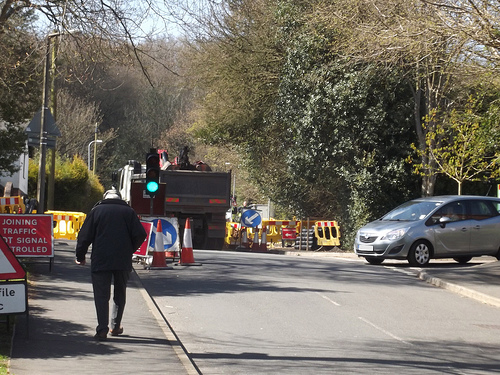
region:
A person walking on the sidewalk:
[74, 181, 149, 339]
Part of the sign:
[248, 211, 257, 221]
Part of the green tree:
[306, 165, 358, 198]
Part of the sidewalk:
[63, 350, 99, 364]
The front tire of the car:
[408, 238, 433, 267]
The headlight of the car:
[378, 227, 408, 242]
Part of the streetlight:
[93, 136, 104, 145]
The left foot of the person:
[93, 323, 110, 340]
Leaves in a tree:
[362, 50, 407, 78]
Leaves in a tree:
[333, 173, 405, 209]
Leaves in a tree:
[356, 144, 418, 183]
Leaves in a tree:
[282, 137, 347, 172]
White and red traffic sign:
[6, 211, 64, 272]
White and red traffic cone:
[178, 216, 192, 265]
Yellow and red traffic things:
[225, 211, 335, 253]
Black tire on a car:
[408, 243, 428, 262]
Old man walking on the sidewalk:
[74, 186, 143, 338]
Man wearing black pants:
[87, 263, 137, 338]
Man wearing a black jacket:
[75, 193, 150, 269]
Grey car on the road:
[350, 183, 498, 280]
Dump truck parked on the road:
[112, 148, 239, 250]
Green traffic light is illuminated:
[140, 150, 167, 204]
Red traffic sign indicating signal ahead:
[0, 206, 60, 266]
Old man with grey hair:
[104, 190, 120, 202]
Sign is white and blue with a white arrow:
[239, 205, 264, 230]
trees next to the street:
[202, 51, 404, 146]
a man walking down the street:
[75, 186, 155, 330]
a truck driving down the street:
[117, 156, 232, 225]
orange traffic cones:
[148, 213, 204, 270]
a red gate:
[256, 215, 331, 228]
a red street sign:
[3, 214, 56, 256]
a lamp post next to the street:
[76, 127, 119, 189]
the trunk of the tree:
[411, 97, 446, 194]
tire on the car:
[411, 236, 433, 262]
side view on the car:
[435, 218, 450, 227]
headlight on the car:
[383, 226, 405, 238]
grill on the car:
[353, 225, 378, 243]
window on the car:
[435, 205, 462, 226]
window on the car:
[473, 202, 497, 217]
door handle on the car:
[460, 225, 469, 232]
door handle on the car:
[473, 225, 480, 232]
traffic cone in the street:
[179, 220, 206, 267]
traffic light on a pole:
[143, 147, 160, 196]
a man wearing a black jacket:
[75, 188, 147, 342]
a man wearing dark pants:
[74, 187, 146, 341]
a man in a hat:
[76, 188, 148, 340]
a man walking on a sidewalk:
[8, 190, 198, 374]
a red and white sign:
[0, 213, 54, 257]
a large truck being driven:
[116, 144, 232, 248]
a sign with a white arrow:
[241, 205, 259, 227]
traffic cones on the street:
[137, 218, 499, 374]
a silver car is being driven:
[354, 194, 499, 262]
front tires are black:
[363, 241, 429, 266]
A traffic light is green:
[137, 141, 163, 201]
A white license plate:
[351, 237, 372, 253]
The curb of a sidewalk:
[410, 260, 495, 307]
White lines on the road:
[305, 280, 470, 370]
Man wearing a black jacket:
[70, 182, 150, 277]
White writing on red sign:
[0, 210, 57, 260]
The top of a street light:
[81, 130, 106, 175]